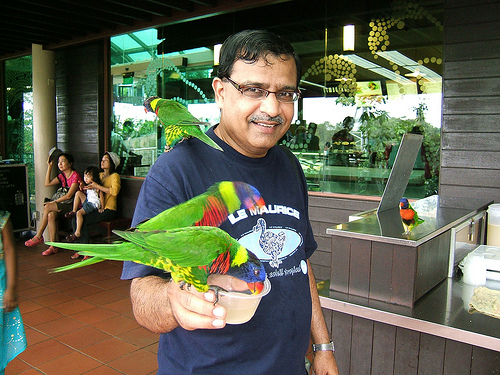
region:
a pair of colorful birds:
[39, 176, 276, 304]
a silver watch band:
[311, 338, 341, 355]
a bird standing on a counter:
[333, 188, 490, 248]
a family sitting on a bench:
[31, 140, 125, 262]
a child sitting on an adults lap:
[68, 140, 120, 252]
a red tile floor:
[25, 276, 135, 370]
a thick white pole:
[26, 75, 58, 248]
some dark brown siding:
[442, 73, 494, 197]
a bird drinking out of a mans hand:
[58, 225, 273, 325]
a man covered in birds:
[89, 25, 351, 369]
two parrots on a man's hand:
[106, 177, 291, 311]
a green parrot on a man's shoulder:
[137, 83, 214, 162]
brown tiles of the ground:
[51, 302, 113, 364]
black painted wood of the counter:
[342, 250, 411, 303]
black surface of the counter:
[431, 297, 466, 330]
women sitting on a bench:
[33, 145, 120, 259]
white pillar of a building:
[25, 63, 66, 218]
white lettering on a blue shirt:
[227, 198, 307, 226]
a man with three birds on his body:
[111, 50, 356, 370]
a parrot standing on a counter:
[384, 183, 439, 241]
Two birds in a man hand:
[114, 197, 344, 339]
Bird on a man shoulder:
[139, 88, 226, 153]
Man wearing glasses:
[224, 70, 352, 122]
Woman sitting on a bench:
[38, 142, 76, 204]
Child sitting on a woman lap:
[82, 168, 97, 221]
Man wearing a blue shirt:
[169, 215, 304, 327]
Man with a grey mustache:
[245, 111, 300, 150]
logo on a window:
[315, 52, 400, 142]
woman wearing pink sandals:
[16, 229, 68, 280]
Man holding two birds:
[111, 198, 276, 303]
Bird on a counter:
[388, 182, 427, 242]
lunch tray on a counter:
[447, 221, 498, 297]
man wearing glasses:
[213, 64, 305, 140]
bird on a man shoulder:
[130, 82, 205, 175]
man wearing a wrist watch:
[301, 323, 357, 368]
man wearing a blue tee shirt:
[168, 139, 323, 329]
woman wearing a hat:
[100, 147, 143, 187]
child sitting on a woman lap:
[78, 175, 100, 215]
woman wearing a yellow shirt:
[93, 170, 116, 202]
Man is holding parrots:
[45, 30, 338, 372]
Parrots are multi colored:
[45, 182, 263, 294]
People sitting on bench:
[22, 147, 119, 259]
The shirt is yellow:
[97, 170, 117, 210]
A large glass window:
[110, 1, 443, 200]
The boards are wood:
[308, 308, 498, 373]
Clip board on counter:
[377, 127, 425, 212]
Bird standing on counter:
[400, 197, 423, 234]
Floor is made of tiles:
[0, 239, 160, 373]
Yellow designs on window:
[301, 13, 441, 95]